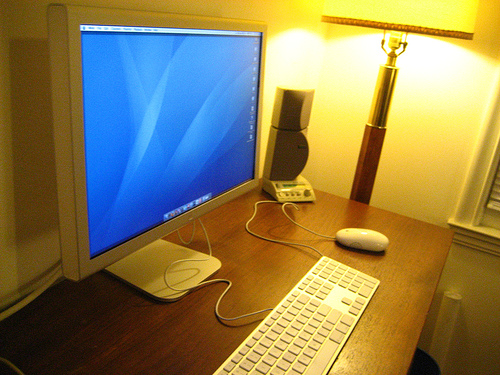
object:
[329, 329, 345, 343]
button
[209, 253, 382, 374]
keyboard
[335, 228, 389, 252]
mouse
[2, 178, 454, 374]
desk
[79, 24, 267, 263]
monitor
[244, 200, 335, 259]
cord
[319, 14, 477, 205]
lamp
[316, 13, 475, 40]
lamp shade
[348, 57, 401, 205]
lamp pole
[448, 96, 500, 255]
window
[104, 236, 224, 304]
stand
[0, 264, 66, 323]
wire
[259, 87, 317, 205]
speaker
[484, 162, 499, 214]
blinds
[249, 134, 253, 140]
icon